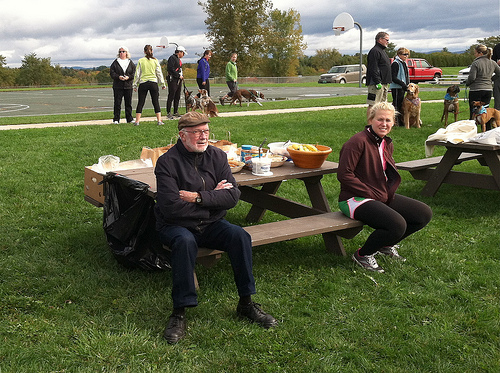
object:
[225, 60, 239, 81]
jacket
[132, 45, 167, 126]
woman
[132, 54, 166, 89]
yellow shirt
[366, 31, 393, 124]
man's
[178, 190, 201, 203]
hand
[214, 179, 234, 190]
hand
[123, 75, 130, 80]
hand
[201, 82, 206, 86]
hand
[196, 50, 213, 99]
man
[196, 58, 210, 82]
blue shirt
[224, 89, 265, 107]
dog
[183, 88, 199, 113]
dog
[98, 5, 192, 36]
clouds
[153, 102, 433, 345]
two people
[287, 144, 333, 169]
bowl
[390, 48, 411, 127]
woman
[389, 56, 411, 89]
vest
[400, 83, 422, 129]
dog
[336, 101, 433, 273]
woman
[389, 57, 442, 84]
truck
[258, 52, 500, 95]
parking lot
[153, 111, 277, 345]
gentleman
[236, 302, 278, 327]
foot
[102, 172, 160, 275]
garbage bag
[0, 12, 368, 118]
basketball court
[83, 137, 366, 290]
picnic table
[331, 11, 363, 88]
basketball goa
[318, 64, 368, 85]
car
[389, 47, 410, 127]
owner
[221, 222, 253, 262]
knee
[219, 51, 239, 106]
person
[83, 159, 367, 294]
bench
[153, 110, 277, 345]
man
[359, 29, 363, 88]
pole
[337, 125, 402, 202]
jacket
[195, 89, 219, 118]
dog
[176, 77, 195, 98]
leash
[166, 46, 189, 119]
man